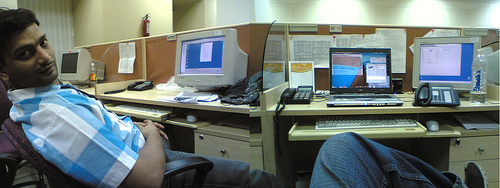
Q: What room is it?
A: It is an office.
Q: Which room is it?
A: It is an office.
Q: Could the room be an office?
A: Yes, it is an office.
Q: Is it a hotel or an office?
A: It is an office.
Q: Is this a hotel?
A: No, it is an office.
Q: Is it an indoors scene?
A: Yes, it is indoors.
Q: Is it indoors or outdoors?
A: It is indoors.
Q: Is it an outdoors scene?
A: No, it is indoors.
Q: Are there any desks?
A: Yes, there is a desk.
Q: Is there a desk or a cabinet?
A: Yes, there is a desk.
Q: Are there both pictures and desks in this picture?
A: No, there is a desk but no pictures.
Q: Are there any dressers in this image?
A: No, there are no dressers.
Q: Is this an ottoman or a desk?
A: This is a desk.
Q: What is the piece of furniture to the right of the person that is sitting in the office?
A: The piece of furniture is a desk.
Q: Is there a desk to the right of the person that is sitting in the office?
A: Yes, there is a desk to the right of the person.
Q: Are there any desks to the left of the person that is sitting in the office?
A: No, the desk is to the right of the person.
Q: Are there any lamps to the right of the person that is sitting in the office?
A: No, there is a desk to the right of the person.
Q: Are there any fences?
A: No, there are no fences.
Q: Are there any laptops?
A: Yes, there is a laptop.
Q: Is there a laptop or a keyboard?
A: Yes, there is a laptop.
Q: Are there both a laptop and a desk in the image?
A: Yes, there are both a laptop and a desk.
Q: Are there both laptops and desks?
A: Yes, there are both a laptop and a desk.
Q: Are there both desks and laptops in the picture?
A: Yes, there are both a laptop and a desk.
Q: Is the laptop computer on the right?
A: Yes, the laptop computer is on the right of the image.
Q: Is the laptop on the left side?
A: No, the laptop is on the right of the image.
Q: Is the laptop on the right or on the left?
A: The laptop is on the right of the image.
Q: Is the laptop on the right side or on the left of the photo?
A: The laptop is on the right of the image.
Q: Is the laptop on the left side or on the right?
A: The laptop is on the right of the image.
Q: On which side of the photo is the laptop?
A: The laptop is on the right of the image.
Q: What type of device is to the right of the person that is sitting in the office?
A: The device is a laptop.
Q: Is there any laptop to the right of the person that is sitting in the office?
A: Yes, there is a laptop to the right of the person.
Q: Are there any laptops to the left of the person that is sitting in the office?
A: No, the laptop is to the right of the person.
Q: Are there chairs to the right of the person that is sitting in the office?
A: No, there is a laptop to the right of the person.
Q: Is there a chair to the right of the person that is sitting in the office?
A: No, there is a laptop to the right of the person.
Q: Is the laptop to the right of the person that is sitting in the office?
A: Yes, the laptop is to the right of the person.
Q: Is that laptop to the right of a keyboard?
A: No, the laptop is to the right of the person.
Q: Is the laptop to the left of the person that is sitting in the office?
A: No, the laptop is to the right of the person.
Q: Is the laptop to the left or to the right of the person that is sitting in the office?
A: The laptop is to the right of the person.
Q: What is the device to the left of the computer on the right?
A: The device is a laptop.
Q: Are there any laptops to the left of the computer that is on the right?
A: Yes, there is a laptop to the left of the computer.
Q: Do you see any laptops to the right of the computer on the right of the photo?
A: No, the laptop is to the left of the computer.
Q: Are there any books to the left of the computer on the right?
A: No, there is a laptop to the left of the computer.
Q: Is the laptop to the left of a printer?
A: No, the laptop is to the left of a computer.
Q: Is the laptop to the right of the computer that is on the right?
A: No, the laptop is to the left of the computer.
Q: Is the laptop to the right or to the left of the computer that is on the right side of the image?
A: The laptop is to the left of the computer.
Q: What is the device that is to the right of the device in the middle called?
A: The device is a laptop.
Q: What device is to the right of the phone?
A: The device is a laptop.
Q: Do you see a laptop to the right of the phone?
A: Yes, there is a laptop to the right of the phone.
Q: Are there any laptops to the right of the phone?
A: Yes, there is a laptop to the right of the phone.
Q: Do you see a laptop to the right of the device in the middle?
A: Yes, there is a laptop to the right of the phone.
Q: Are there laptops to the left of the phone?
A: No, the laptop is to the right of the phone.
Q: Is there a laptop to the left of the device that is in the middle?
A: No, the laptop is to the right of the phone.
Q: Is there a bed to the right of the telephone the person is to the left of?
A: No, there is a laptop to the right of the phone.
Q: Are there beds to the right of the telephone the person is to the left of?
A: No, there is a laptop to the right of the phone.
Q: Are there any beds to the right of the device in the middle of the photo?
A: No, there is a laptop to the right of the phone.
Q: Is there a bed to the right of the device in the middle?
A: No, there is a laptop to the right of the phone.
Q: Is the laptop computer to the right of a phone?
A: Yes, the laptop computer is to the right of a phone.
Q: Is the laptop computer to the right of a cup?
A: No, the laptop computer is to the right of a phone.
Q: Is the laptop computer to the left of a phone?
A: No, the laptop computer is to the right of a phone.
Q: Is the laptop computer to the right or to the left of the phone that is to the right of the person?
A: The laptop computer is to the right of the telephone.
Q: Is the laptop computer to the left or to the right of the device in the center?
A: The laptop computer is to the right of the telephone.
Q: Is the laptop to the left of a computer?
A: No, the laptop is to the right of a computer.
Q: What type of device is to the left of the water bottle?
A: The device is a laptop.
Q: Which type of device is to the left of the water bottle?
A: The device is a laptop.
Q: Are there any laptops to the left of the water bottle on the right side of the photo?
A: Yes, there is a laptop to the left of the water bottle.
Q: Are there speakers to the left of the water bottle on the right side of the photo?
A: No, there is a laptop to the left of the water bottle.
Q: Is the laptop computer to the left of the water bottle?
A: Yes, the laptop computer is to the left of the water bottle.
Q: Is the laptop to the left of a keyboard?
A: No, the laptop is to the left of the water bottle.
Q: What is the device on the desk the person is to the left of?
A: The device is a laptop.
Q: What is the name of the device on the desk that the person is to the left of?
A: The device is a laptop.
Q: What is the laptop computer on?
A: The laptop computer is on the desk.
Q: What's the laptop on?
A: The laptop computer is on the desk.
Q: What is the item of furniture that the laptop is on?
A: The piece of furniture is a desk.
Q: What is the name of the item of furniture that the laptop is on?
A: The piece of furniture is a desk.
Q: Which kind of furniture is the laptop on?
A: The laptop is on the desk.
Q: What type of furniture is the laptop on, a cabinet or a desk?
A: The laptop is on a desk.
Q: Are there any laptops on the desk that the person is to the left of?
A: Yes, there is a laptop on the desk.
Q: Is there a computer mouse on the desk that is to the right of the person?
A: No, there is a laptop on the desk.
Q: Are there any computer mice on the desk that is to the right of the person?
A: No, there is a laptop on the desk.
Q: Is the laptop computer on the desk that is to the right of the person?
A: Yes, the laptop computer is on the desk.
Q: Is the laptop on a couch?
A: No, the laptop is on the desk.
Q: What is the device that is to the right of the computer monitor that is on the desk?
A: The device is a laptop.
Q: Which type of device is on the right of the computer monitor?
A: The device is a laptop.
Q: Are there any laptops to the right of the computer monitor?
A: Yes, there is a laptop to the right of the computer monitor.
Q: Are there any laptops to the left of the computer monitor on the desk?
A: No, the laptop is to the right of the computer monitor.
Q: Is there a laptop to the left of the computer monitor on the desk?
A: No, the laptop is to the right of the computer monitor.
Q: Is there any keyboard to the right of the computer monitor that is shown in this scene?
A: No, there is a laptop to the right of the computer monitor.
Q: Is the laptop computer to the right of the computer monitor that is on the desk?
A: Yes, the laptop computer is to the right of the computer monitor.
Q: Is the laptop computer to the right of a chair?
A: No, the laptop computer is to the right of the computer monitor.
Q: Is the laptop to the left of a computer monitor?
A: No, the laptop is to the right of a computer monitor.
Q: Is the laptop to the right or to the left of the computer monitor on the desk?
A: The laptop is to the right of the computer monitor.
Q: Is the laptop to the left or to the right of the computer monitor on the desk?
A: The laptop is to the right of the computer monitor.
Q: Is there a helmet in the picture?
A: No, there are no helmets.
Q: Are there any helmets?
A: No, there are no helmets.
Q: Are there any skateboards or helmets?
A: No, there are no helmets or skateboards.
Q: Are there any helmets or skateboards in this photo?
A: No, there are no helmets or skateboards.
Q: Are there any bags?
A: No, there are no bags.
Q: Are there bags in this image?
A: No, there are no bags.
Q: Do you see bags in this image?
A: No, there are no bags.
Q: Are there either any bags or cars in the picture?
A: No, there are no bags or cars.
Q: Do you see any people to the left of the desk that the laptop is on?
A: Yes, there is a person to the left of the desk.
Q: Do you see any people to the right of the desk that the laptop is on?
A: No, the person is to the left of the desk.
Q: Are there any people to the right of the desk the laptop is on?
A: No, the person is to the left of the desk.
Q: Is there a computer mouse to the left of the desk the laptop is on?
A: No, there is a person to the left of the desk.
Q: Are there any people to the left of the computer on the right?
A: Yes, there is a person to the left of the computer.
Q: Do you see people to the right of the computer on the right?
A: No, the person is to the left of the computer.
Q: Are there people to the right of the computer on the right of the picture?
A: No, the person is to the left of the computer.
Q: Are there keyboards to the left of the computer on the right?
A: No, there is a person to the left of the computer.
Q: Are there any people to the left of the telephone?
A: Yes, there is a person to the left of the telephone.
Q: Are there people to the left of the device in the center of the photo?
A: Yes, there is a person to the left of the telephone.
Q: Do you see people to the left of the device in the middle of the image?
A: Yes, there is a person to the left of the telephone.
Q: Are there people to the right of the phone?
A: No, the person is to the left of the phone.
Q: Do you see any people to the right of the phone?
A: No, the person is to the left of the phone.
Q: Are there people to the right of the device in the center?
A: No, the person is to the left of the phone.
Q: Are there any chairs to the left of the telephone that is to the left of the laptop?
A: No, there is a person to the left of the telephone.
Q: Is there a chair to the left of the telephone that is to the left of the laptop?
A: No, there is a person to the left of the telephone.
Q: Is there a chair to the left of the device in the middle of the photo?
A: No, there is a person to the left of the telephone.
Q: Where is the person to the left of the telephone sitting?
A: The person is sitting in the office.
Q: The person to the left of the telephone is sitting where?
A: The person is sitting in the office.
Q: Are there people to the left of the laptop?
A: Yes, there is a person to the left of the laptop.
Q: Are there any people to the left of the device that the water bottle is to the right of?
A: Yes, there is a person to the left of the laptop.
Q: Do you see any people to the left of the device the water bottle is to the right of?
A: Yes, there is a person to the left of the laptop.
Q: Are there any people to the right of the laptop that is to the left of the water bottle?
A: No, the person is to the left of the laptop.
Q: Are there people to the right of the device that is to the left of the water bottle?
A: No, the person is to the left of the laptop.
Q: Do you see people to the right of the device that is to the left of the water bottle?
A: No, the person is to the left of the laptop.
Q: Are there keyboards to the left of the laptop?
A: No, there is a person to the left of the laptop.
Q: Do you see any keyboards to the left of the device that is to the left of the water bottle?
A: No, there is a person to the left of the laptop.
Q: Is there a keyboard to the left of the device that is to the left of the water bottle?
A: No, there is a person to the left of the laptop.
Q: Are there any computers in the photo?
A: Yes, there is a computer.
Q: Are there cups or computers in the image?
A: Yes, there is a computer.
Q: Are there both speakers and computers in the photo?
A: No, there is a computer but no speakers.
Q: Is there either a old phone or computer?
A: Yes, there is an old computer.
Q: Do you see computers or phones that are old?
A: Yes, the computer is old.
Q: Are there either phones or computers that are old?
A: Yes, the computer is old.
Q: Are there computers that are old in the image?
A: Yes, there is an old computer.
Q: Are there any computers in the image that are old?
A: Yes, there is a computer that is old.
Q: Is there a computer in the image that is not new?
A: Yes, there is a old computer.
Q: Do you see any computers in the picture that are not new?
A: Yes, there is a old computer.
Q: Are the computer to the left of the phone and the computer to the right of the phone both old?
A: Yes, both the computer and the computer are old.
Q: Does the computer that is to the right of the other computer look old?
A: Yes, the computer is old.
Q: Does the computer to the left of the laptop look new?
A: No, the computer is old.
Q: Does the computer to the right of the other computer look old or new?
A: The computer is old.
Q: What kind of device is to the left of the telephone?
A: The device is a computer.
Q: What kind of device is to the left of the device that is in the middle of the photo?
A: The device is a computer.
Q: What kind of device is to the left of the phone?
A: The device is a computer.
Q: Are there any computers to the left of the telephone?
A: Yes, there is a computer to the left of the telephone.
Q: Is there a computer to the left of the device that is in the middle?
A: Yes, there is a computer to the left of the telephone.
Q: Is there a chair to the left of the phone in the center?
A: No, there is a computer to the left of the telephone.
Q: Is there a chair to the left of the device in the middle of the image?
A: No, there is a computer to the left of the telephone.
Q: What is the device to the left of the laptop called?
A: The device is a computer.